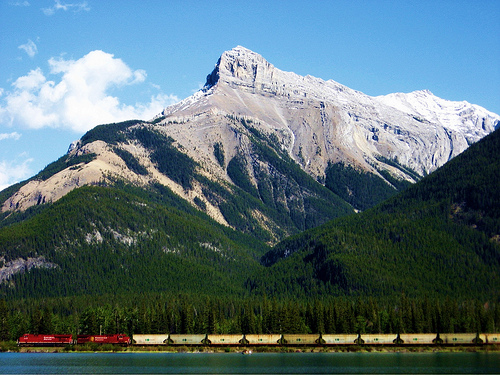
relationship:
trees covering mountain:
[4, 122, 499, 335] [0, 45, 493, 292]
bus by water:
[16, 333, 500, 348] [0, 351, 498, 373]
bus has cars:
[16, 333, 500, 348] [22, 333, 179, 350]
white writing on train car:
[42, 335, 56, 342] [16, 331, 77, 346]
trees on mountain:
[111, 189, 222, 272] [0, 45, 499, 330]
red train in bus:
[14, 331, 134, 348] [127, 320, 479, 365]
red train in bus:
[25, 330, 87, 357] [127, 320, 477, 340]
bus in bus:
[16, 333, 500, 348] [16, 317, 141, 352]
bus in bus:
[16, 333, 500, 348] [9, 320, 133, 350]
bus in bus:
[16, 333, 500, 348] [10, 318, 128, 351]